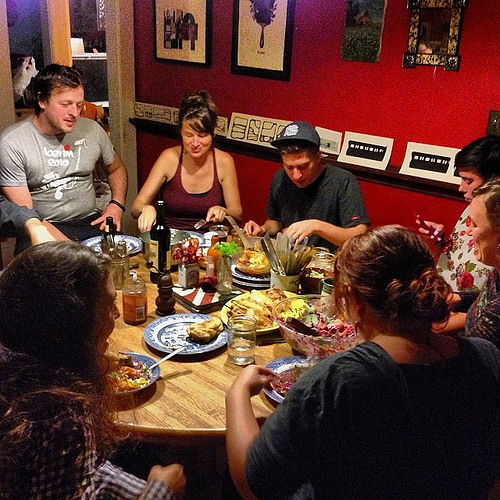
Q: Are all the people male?
A: No, they are both male and female.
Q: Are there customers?
A: No, there are no customers.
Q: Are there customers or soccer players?
A: No, there are no customers or soccer players.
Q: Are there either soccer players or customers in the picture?
A: No, there are no customers or soccer players.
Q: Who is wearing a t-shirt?
A: The man is wearing a t-shirt.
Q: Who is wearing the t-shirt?
A: The man is wearing a t-shirt.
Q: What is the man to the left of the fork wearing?
A: The man is wearing a tee shirt.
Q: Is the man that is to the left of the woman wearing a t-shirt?
A: Yes, the man is wearing a t-shirt.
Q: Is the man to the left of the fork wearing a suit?
A: No, the man is wearing a t-shirt.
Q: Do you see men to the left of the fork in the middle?
A: Yes, there is a man to the left of the fork.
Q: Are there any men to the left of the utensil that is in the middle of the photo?
A: Yes, there is a man to the left of the fork.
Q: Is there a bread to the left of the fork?
A: No, there is a man to the left of the fork.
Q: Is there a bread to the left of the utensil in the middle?
A: No, there is a man to the left of the fork.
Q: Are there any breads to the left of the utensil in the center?
A: No, there is a man to the left of the fork.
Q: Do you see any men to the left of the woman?
A: Yes, there is a man to the left of the woman.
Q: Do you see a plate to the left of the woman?
A: No, there is a man to the left of the woman.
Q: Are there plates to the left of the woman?
A: No, there is a man to the left of the woman.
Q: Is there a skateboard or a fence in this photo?
A: No, there are no fences or skateboards.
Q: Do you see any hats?
A: Yes, there is a hat.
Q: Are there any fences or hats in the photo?
A: Yes, there is a hat.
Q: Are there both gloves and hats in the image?
A: No, there is a hat but no gloves.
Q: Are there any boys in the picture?
A: No, there are no boys.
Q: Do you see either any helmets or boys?
A: No, there are no boys or helmets.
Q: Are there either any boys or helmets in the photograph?
A: No, there are no boys or helmets.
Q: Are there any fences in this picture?
A: No, there are no fences.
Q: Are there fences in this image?
A: No, there are no fences.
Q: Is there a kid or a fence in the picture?
A: No, there are no fences or children.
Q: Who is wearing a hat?
A: The man is wearing a hat.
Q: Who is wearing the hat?
A: The man is wearing a hat.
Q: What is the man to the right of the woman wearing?
A: The man is wearing a hat.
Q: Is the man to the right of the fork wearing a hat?
A: Yes, the man is wearing a hat.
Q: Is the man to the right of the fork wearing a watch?
A: No, the man is wearing a hat.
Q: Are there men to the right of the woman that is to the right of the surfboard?
A: Yes, there is a man to the right of the woman.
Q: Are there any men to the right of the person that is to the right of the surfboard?
A: Yes, there is a man to the right of the woman.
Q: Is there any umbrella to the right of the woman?
A: No, there is a man to the right of the woman.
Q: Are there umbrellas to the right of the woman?
A: No, there is a man to the right of the woman.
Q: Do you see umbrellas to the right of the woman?
A: No, there is a man to the right of the woman.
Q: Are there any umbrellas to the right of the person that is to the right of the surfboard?
A: No, there is a man to the right of the woman.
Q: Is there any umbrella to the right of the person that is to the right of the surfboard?
A: No, there is a man to the right of the woman.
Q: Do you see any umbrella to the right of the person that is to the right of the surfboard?
A: No, there is a man to the right of the woman.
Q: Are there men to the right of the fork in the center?
A: Yes, there is a man to the right of the fork.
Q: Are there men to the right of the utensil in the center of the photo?
A: Yes, there is a man to the right of the fork.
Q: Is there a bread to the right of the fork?
A: No, there is a man to the right of the fork.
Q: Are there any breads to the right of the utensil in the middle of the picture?
A: No, there is a man to the right of the fork.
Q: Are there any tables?
A: Yes, there is a table.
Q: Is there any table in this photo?
A: Yes, there is a table.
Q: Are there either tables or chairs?
A: Yes, there is a table.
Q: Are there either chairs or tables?
A: Yes, there is a table.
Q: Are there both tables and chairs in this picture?
A: No, there is a table but no chairs.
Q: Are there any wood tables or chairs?
A: Yes, there is a wood table.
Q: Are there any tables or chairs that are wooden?
A: Yes, the table is wooden.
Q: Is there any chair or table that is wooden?
A: Yes, the table is wooden.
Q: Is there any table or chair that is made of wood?
A: Yes, the table is made of wood.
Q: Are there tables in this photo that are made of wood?
A: Yes, there is a table that is made of wood.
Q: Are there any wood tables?
A: Yes, there is a table that is made of wood.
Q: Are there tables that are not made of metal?
A: Yes, there is a table that is made of wood.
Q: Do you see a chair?
A: No, there are no chairs.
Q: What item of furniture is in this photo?
A: The piece of furniture is a table.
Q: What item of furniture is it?
A: The piece of furniture is a table.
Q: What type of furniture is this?
A: This is a table.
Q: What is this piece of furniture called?
A: This is a table.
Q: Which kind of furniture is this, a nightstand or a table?
A: This is a table.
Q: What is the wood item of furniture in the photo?
A: The piece of furniture is a table.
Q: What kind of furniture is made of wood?
A: The furniture is a table.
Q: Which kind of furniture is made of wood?
A: The furniture is a table.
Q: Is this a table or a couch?
A: This is a table.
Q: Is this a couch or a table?
A: This is a table.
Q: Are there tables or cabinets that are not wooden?
A: No, there is a table but it is wooden.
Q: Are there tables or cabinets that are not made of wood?
A: No, there is a table but it is made of wood.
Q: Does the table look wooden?
A: Yes, the table is wooden.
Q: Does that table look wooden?
A: Yes, the table is wooden.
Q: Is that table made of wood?
A: Yes, the table is made of wood.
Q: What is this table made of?
A: The table is made of wood.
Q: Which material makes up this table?
A: The table is made of wood.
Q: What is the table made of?
A: The table is made of wood.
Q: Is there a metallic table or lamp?
A: No, there is a table but it is wooden.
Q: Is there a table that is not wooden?
A: No, there is a table but it is wooden.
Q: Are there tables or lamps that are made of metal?
A: No, there is a table but it is made of wood.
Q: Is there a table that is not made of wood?
A: No, there is a table but it is made of wood.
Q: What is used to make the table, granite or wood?
A: The table is made of wood.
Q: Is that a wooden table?
A: Yes, that is a wooden table.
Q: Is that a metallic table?
A: No, that is a wooden table.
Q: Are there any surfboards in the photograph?
A: Yes, there is a surfboard.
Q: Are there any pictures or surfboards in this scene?
A: Yes, there is a surfboard.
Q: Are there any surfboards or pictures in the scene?
A: Yes, there is a surfboard.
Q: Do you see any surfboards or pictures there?
A: Yes, there is a surfboard.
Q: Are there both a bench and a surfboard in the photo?
A: No, there is a surfboard but no benches.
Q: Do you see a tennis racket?
A: No, there are no rackets.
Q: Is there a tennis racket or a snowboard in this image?
A: No, there are no rackets or snowboards.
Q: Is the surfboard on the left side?
A: Yes, the surfboard is on the left of the image.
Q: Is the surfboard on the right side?
A: No, the surfboard is on the left of the image.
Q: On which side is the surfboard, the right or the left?
A: The surfboard is on the left of the image.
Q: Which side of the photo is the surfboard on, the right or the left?
A: The surfboard is on the left of the image.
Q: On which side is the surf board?
A: The surf board is on the left of the image.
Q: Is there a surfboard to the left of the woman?
A: Yes, there is a surfboard to the left of the woman.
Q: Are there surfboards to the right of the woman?
A: No, the surfboard is to the left of the woman.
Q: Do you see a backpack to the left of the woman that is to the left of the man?
A: No, there is a surfboard to the left of the woman.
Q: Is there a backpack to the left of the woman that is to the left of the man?
A: No, there is a surfboard to the left of the woman.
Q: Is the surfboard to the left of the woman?
A: Yes, the surfboard is to the left of the woman.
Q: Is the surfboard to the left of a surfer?
A: No, the surfboard is to the left of the woman.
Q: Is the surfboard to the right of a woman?
A: No, the surfboard is to the left of a woman.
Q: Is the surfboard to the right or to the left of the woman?
A: The surfboard is to the left of the woman.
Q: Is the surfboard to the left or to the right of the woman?
A: The surfboard is to the left of the woman.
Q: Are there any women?
A: Yes, there is a woman.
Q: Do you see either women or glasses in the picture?
A: Yes, there is a woman.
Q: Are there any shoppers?
A: No, there are no shoppers.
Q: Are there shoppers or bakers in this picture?
A: No, there are no shoppers or bakers.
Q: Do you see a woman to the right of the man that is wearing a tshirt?
A: Yes, there is a woman to the right of the man.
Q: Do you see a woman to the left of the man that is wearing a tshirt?
A: No, the woman is to the right of the man.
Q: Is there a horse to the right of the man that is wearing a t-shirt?
A: No, there is a woman to the right of the man.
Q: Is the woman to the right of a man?
A: Yes, the woman is to the right of a man.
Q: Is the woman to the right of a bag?
A: No, the woman is to the right of a man.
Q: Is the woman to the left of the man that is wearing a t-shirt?
A: No, the woman is to the right of the man.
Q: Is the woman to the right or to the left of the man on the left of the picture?
A: The woman is to the right of the man.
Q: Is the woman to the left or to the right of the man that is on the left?
A: The woman is to the right of the man.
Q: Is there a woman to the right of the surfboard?
A: Yes, there is a woman to the right of the surfboard.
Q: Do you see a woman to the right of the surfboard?
A: Yes, there is a woman to the right of the surfboard.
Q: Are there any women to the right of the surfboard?
A: Yes, there is a woman to the right of the surfboard.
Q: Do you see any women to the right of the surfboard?
A: Yes, there is a woman to the right of the surfboard.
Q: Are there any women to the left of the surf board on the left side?
A: No, the woman is to the right of the surfboard.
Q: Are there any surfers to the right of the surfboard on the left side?
A: No, there is a woman to the right of the surf board.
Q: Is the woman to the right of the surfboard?
A: Yes, the woman is to the right of the surfboard.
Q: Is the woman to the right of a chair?
A: No, the woman is to the right of the surfboard.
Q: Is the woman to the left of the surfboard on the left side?
A: No, the woman is to the right of the surfboard.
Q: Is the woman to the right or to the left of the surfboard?
A: The woman is to the right of the surfboard.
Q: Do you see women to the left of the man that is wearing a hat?
A: Yes, there is a woman to the left of the man.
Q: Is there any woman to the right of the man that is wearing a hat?
A: No, the woman is to the left of the man.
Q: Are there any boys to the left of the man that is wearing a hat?
A: No, there is a woman to the left of the man.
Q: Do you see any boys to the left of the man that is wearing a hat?
A: No, there is a woman to the left of the man.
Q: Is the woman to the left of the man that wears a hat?
A: Yes, the woman is to the left of the man.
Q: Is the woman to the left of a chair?
A: No, the woman is to the left of the man.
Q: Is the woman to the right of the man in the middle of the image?
A: No, the woman is to the left of the man.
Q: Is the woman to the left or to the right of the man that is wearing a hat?
A: The woman is to the left of the man.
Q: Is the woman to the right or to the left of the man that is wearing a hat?
A: The woman is to the left of the man.